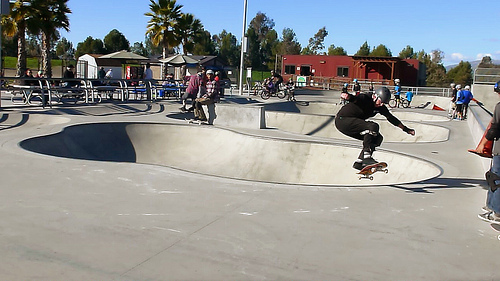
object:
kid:
[393, 79, 403, 108]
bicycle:
[388, 95, 410, 108]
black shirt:
[336, 91, 401, 126]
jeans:
[335, 116, 384, 160]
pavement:
[165, 249, 233, 280]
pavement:
[436, 141, 464, 188]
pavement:
[8, 109, 66, 126]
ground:
[362, 150, 435, 210]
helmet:
[372, 87, 391, 104]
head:
[372, 86, 392, 107]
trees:
[247, 10, 283, 71]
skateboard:
[356, 162, 388, 181]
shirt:
[202, 80, 220, 103]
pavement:
[387, 258, 498, 279]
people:
[192, 70, 220, 125]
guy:
[266, 70, 284, 94]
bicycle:
[260, 82, 286, 99]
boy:
[403, 88, 414, 108]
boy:
[335, 87, 415, 181]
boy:
[461, 85, 473, 120]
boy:
[453, 84, 464, 121]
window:
[336, 65, 349, 77]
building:
[281, 54, 427, 95]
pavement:
[2, 170, 48, 186]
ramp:
[16, 121, 444, 187]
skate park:
[0, 85, 500, 281]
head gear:
[373, 86, 391, 103]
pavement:
[118, 221, 135, 267]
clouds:
[386, 20, 456, 48]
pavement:
[265, 189, 307, 208]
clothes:
[335, 92, 401, 160]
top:
[455, 90, 465, 105]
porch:
[354, 59, 397, 86]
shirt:
[183, 73, 204, 94]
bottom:
[356, 162, 389, 181]